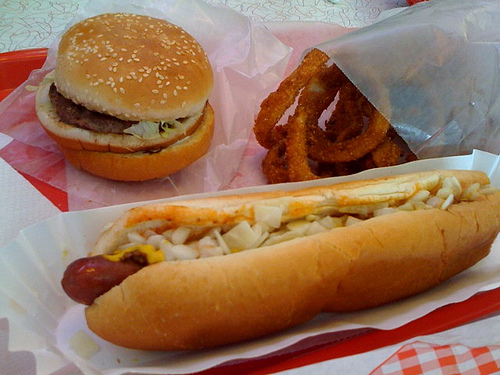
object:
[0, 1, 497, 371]
white paper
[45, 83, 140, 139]
burger pattie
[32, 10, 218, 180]
burger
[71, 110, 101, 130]
sausage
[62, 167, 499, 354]
hot dog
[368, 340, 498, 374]
paper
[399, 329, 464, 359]
tablecloth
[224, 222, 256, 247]
onion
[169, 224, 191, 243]
onion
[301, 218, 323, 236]
onion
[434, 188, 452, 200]
onion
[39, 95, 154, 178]
patty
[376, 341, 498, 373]
table cloth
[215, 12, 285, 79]
clear paper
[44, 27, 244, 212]
hamburger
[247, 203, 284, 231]
onion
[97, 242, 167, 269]
mustard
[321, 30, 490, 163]
bag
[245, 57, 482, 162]
rings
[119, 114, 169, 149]
lettuce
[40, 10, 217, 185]
sandwich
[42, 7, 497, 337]
lunch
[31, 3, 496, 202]
wax paper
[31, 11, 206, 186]
train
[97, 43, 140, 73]
seeds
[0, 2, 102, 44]
table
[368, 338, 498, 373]
checkered cloth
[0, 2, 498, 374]
tray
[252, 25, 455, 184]
onion rings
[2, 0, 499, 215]
wrapper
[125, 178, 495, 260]
onions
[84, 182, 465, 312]
food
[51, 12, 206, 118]
bun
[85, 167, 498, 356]
roll